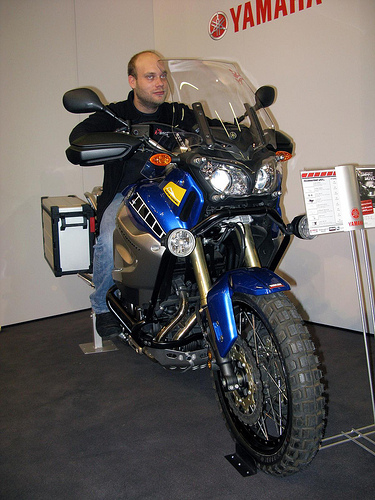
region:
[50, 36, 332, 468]
man is sitting on a bike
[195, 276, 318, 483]
the wheel is black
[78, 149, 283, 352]
the bike is blue and grey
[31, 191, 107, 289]
a box on the side of the bike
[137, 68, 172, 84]
the eyes are open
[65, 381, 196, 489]
the ground is dark grey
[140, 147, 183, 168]
the signal light is orange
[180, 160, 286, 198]
the headlights are on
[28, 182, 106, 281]
the box is white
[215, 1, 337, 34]
the letters are red on the wall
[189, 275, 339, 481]
front wheel of motorcycle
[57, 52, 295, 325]
man wears a black jacket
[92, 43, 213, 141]
man has green eyes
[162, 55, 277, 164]
windshield of motorcycle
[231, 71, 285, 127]
mirror on right side of motorcycle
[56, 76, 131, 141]
mirror on right side of motorcycle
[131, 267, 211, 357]
engine of motorcycle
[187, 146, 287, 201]
headlights of motorcycle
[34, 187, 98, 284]
white box on motorcycle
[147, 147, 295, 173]
orange lights on motorcycle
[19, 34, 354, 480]
man on a motor cycle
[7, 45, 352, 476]
man wearing black jacket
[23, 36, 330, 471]
man wearing blue jeans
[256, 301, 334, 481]
tire on a motor cycle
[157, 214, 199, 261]
light on a motor cycle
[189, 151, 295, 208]
light on a motor cycle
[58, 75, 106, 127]
mirror on a motor cycle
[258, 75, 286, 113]
mirror on a motor cycle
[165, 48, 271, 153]
window on a motor cycle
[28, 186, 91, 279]
storage box on motor cycle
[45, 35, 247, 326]
this is a man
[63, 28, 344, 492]
this is a bike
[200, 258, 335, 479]
this is a wheel of a bike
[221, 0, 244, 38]
this is a letter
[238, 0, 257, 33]
this is a letter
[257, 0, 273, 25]
this is a letter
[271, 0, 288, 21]
this is a letter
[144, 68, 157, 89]
the eye of a man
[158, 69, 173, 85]
the eye of a man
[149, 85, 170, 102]
the mouth of a man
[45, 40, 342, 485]
man wears a black jacket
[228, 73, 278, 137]
a black mirror on right side of motorcycle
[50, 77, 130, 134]
a black mirror on left side of motorcycle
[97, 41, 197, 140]
man has blue eyes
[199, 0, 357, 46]
red letters on wall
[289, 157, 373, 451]
stand displays a catalog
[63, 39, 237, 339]
man wears blue jeans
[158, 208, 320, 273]
side front lights on motorcycle